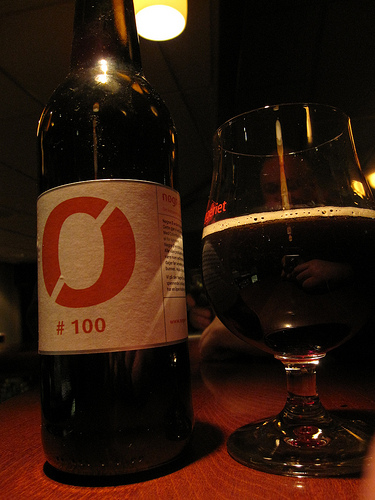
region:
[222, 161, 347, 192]
A wine glass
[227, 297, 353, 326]
Bottom of the glass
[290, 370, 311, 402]
The stem of the wine glass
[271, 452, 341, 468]
Base of the wine glass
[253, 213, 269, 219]
Foam from the contents in the glass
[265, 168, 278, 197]
Face of person through the glass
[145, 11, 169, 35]
Light in a lamp shade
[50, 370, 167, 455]
A bottle on the table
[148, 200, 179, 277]
A label on the bottle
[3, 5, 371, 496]
A beautiful scene with Alcohol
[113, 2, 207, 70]
A yellow light is glowing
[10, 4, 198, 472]
A big bottle is on the table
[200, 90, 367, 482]
A wine glass in kept on the table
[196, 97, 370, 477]
A foam is appeared in the glass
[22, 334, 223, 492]
Shadow of the bottle appears on the table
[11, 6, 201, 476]
The bottle neck is like hen's neck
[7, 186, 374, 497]
Wooden table is in red color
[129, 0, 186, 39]
circle of white light within yellow shade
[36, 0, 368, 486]
bottle and stemmed glass side by side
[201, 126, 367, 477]
dark liquid inside glass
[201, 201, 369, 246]
tan and bubbly foam on top of liquid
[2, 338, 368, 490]
wooden tables with light swirling lines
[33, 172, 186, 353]
tan and red label over bottle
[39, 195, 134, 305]
two red arcs forming a broken circle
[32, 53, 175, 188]
light reflecting off curved bottle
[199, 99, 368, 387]
glass partially filled with drink